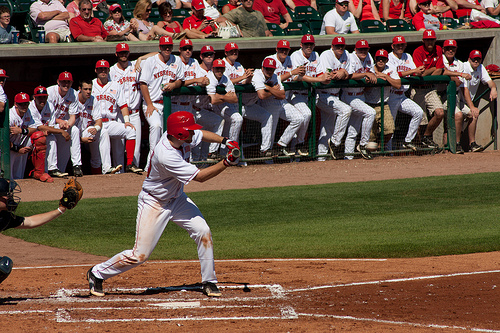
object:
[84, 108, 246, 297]
batter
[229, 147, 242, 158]
bat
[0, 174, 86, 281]
catcher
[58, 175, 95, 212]
catchers mitt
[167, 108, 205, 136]
red helmet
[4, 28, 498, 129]
players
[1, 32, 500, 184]
dugout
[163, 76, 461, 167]
fence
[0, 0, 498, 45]
audience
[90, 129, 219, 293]
uniform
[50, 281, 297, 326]
home plate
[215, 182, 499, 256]
grass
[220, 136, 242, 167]
gloves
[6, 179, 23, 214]
faceguard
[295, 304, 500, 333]
chalk lines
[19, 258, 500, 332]
dirt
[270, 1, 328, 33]
bleachers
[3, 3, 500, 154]
sidelines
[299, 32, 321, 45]
hat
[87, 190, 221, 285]
pants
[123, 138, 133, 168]
socks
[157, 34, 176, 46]
hats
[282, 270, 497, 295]
lines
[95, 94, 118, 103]
lettering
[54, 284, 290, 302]
batter box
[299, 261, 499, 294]
third base line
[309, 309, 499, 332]
first base line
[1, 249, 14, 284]
leg guards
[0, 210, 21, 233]
black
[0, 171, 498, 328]
baseball field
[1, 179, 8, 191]
hat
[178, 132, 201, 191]
short sleeves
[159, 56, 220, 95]
shirts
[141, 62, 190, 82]
short sleeves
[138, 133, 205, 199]
jersey